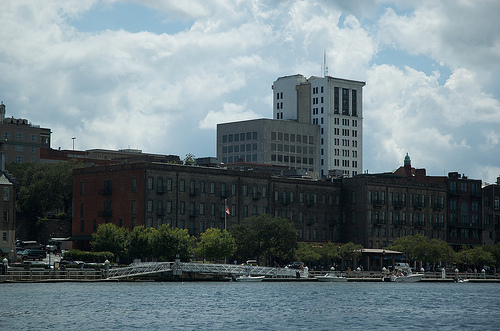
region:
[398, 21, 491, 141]
this is the sky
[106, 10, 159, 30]
the sky is blue in color r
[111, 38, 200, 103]
these are the clouds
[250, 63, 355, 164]
this is a building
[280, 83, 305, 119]
this is the wall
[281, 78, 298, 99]
the wall is white in color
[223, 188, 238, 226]
this is a flag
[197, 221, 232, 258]
this is a tree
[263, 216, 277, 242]
the leaves are green in color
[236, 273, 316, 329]
this is a water body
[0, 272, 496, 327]
this is an ocean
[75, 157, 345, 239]
this is a bulding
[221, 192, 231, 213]
this is a flag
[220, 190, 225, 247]
this is a flag post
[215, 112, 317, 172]
this is a bulding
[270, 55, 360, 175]
this is a bulding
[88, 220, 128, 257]
this is a bush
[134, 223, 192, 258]
this is a bush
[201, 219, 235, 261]
this is a bush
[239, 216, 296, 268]
this is a bush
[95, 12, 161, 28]
this is the sky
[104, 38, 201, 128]
the sky has clouds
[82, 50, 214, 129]
the clouds are white in color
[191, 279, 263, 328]
this is the water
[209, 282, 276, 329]
the water is blue in color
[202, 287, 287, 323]
the water has ripples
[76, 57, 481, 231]
these are some buildings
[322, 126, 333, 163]
the building is white in color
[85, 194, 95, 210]
the wall is brown in color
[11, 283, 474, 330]
water in front of buildings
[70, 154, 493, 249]
buildings near the water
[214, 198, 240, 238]
flag on a pole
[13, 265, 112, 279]
rail in front of water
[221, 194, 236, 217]
banner on a pole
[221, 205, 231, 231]
pole with flag on it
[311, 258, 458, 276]
people in front of building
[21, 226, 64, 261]
vehicles on the street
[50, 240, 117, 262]
shrubs near the water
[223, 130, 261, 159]
windows on the building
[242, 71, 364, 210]
this is a building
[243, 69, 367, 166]
the building is tall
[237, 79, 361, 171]
the building is white in color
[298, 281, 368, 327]
this is the water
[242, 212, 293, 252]
the trees are tall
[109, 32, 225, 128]
these are the clouds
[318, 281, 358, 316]
the water is calm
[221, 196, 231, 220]
this is the flag